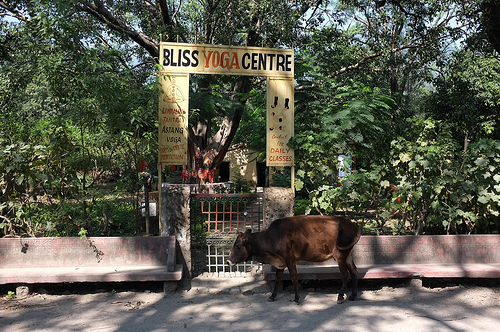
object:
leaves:
[359, 113, 378, 123]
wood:
[78, 134, 94, 209]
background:
[0, 3, 482, 150]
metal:
[205, 219, 222, 258]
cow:
[223, 215, 364, 304]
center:
[150, 35, 301, 295]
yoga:
[200, 50, 242, 70]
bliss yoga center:
[159, 41, 298, 77]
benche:
[1, 234, 184, 298]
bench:
[264, 233, 499, 287]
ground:
[0, 289, 498, 331]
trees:
[0, 0, 495, 226]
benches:
[2, 235, 186, 299]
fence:
[191, 187, 263, 277]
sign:
[156, 40, 296, 166]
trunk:
[207, 77, 253, 183]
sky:
[4, 0, 490, 87]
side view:
[224, 227, 267, 268]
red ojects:
[394, 195, 404, 204]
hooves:
[266, 296, 278, 303]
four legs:
[267, 256, 362, 304]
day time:
[3, 3, 497, 331]